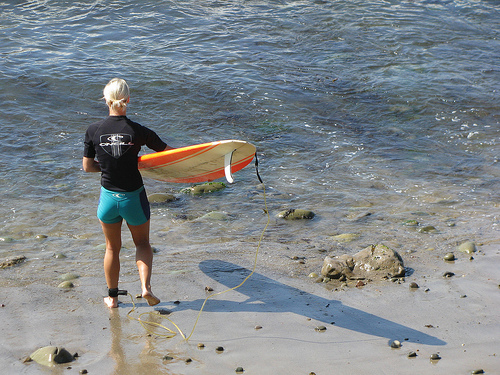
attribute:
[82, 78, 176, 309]
woman — blonde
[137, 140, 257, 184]
surfboard — orange, white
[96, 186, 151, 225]
shorts — blue, tight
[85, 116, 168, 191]
top — black, white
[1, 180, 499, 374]
sand — brown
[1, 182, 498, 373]
rocks — grey, large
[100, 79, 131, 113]
hair — blonde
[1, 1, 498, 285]
water — blue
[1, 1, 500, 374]
beach — sunny